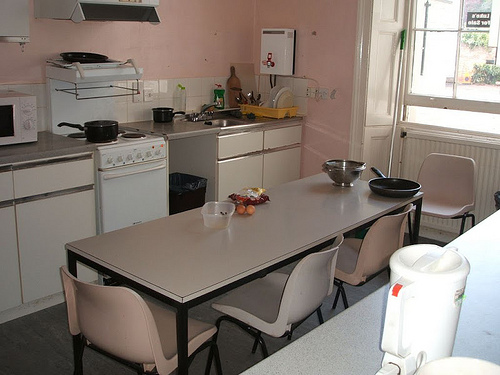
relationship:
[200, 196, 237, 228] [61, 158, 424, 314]
container on table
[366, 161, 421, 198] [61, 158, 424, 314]
pan on table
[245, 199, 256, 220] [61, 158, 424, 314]
orange on table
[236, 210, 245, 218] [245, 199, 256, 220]
orange on orange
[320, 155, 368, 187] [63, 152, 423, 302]
bowl on table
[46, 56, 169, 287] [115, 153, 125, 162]
range with knobs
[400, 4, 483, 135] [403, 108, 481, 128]
window cracked slightly open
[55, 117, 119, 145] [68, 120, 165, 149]
pan on stove top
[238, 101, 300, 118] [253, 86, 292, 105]
drainer with dishes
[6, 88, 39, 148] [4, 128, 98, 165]
microwave on counter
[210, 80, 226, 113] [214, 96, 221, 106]
bottle of detergent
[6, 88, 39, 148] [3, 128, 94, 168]
microwave sits on counter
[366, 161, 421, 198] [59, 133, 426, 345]
pan sits on table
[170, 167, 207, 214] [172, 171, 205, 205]
can with liner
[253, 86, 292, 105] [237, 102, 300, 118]
dishes in rack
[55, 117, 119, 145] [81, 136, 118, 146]
pan sitting on burner